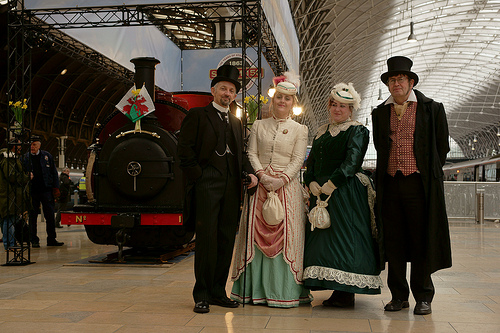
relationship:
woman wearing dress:
[303, 76, 400, 317] [300, 115, 388, 303]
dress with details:
[300, 115, 388, 303] [294, 253, 392, 295]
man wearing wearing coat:
[193, 43, 451, 266] [369, 88, 456, 270]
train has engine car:
[52, 54, 214, 265] [82, 78, 202, 262]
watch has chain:
[226, 142, 233, 152] [213, 147, 225, 157]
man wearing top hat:
[175, 64, 250, 315] [207, 61, 242, 91]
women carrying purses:
[226, 68, 385, 308] [256, 171, 338, 239]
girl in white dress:
[227, 70, 308, 308] [231, 117, 308, 307]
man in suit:
[173, 72, 251, 289] [173, 92, 248, 312]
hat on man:
[208, 64, 248, 86] [195, 63, 242, 299]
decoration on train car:
[110, 83, 155, 120] [59, 56, 203, 258]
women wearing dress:
[226, 78, 386, 307] [244, 115, 310, 309]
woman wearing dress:
[303, 76, 384, 311] [300, 115, 388, 303]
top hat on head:
[377, 54, 422, 88] [382, 71, 416, 96]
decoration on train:
[115, 83, 155, 122] [93, 70, 241, 245]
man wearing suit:
[22, 130, 70, 257] [18, 148, 65, 242]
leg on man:
[185, 197, 222, 303] [179, 65, 259, 317]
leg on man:
[210, 195, 247, 296] [179, 65, 259, 317]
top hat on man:
[208, 65, 244, 87] [189, 60, 246, 307]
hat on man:
[208, 64, 248, 86] [179, 65, 259, 317]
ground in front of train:
[11, 267, 193, 332] [50, 43, 207, 268]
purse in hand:
[259, 188, 290, 230] [259, 171, 289, 192]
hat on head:
[209, 62, 244, 89] [201, 77, 241, 110]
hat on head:
[381, 56, 419, 87] [387, 71, 412, 96]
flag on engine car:
[118, 76, 162, 138] [60, 57, 216, 262]